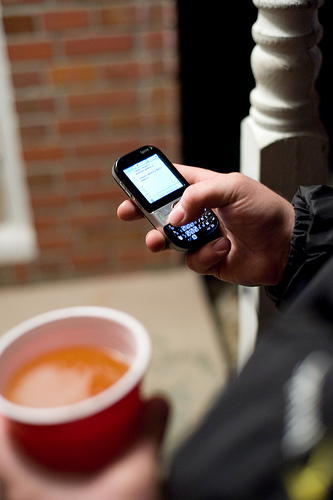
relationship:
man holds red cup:
[0, 164, 332, 499] [0, 302, 151, 476]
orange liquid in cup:
[5, 346, 129, 408] [0, 302, 151, 476]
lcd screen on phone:
[123, 153, 184, 204] [111, 143, 222, 254]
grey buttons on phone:
[155, 209, 169, 224] [111, 143, 222, 254]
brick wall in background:
[0, 1, 187, 288] [1, 1, 330, 467]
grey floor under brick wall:
[1, 262, 230, 475] [0, 1, 187, 288]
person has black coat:
[0, 164, 332, 499] [164, 184, 332, 499]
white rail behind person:
[235, 0, 330, 374] [0, 164, 332, 499]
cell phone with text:
[111, 143, 222, 254] [135, 164, 164, 182]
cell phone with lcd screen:
[111, 143, 222, 254] [123, 153, 184, 204]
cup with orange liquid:
[0, 302, 151, 476] [5, 346, 129, 408]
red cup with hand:
[0, 302, 151, 476] [0, 396, 167, 498]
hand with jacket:
[0, 396, 167, 498] [164, 184, 332, 499]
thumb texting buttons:
[165, 174, 234, 230] [166, 208, 217, 246]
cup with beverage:
[0, 302, 151, 476] [5, 346, 129, 408]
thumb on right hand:
[165, 174, 234, 230] [117, 163, 295, 290]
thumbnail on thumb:
[168, 203, 185, 227] [165, 174, 234, 230]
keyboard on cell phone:
[166, 208, 217, 246] [111, 143, 222, 254]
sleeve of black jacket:
[264, 185, 332, 313] [164, 184, 332, 499]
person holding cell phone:
[0, 164, 332, 499] [111, 143, 222, 254]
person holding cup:
[0, 164, 332, 499] [0, 302, 151, 476]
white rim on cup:
[0, 302, 151, 476] [0, 302, 151, 476]